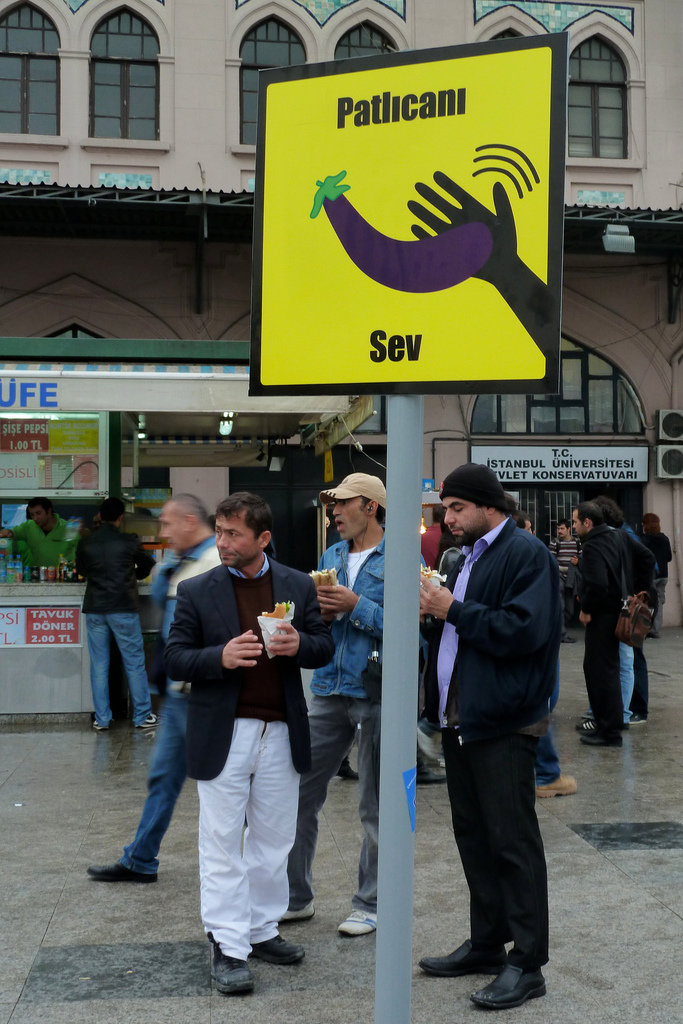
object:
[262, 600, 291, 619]
sandwich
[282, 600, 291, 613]
lettuce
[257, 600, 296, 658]
paper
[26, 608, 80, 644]
sign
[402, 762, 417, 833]
sign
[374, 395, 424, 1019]
pole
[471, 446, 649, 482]
sign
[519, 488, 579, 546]
doorway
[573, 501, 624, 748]
man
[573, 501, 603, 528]
hair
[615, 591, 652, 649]
bag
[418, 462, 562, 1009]
man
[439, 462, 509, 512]
beanie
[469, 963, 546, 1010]
shoe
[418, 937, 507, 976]
shoe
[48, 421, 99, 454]
sign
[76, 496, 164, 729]
man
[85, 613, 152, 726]
jeans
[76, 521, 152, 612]
jacket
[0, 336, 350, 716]
kiosk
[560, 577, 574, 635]
pants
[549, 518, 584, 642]
man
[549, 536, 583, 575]
top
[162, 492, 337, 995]
person